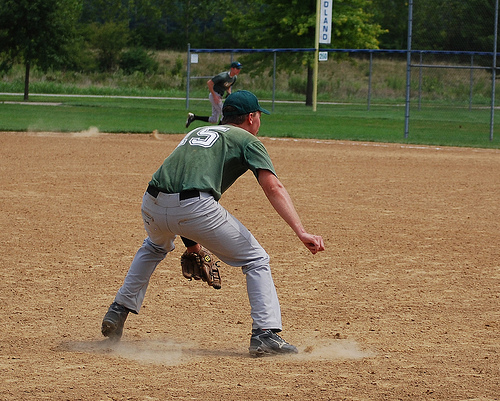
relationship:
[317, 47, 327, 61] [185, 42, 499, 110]
sign on fence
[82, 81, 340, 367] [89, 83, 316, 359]
man in baseball uniform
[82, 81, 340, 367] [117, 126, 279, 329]
man in baseball uniform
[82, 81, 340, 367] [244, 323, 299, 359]
man in shoe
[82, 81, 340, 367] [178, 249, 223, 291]
man holding baseball mit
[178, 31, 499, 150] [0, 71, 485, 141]
fence on other side field